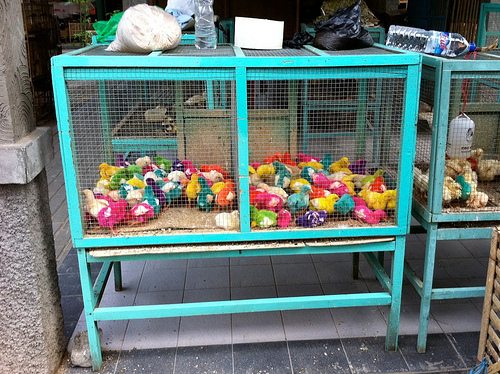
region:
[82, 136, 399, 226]
stuffed animals of all different colors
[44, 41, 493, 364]
two blue cages stuffed animals are in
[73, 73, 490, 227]
wire on the cages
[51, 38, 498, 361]
blue frames of the cages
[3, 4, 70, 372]
cement column next to cage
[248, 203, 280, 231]
green and white stuffed animal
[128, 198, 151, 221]
pink and white stuffed animal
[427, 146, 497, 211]
stuffed teddy bears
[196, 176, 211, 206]
teal and white stuffed animal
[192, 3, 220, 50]
water bottle on top of cage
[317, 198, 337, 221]
baby chick is dyed yellow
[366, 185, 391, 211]
baby chick is dyed yellow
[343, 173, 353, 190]
baby chick is dyed yellow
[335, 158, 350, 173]
baby chick is dyed yellow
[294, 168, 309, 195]
baby chick is dyed yellow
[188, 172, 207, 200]
baby chick is dyed yellow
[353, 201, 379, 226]
baby chick is dyed pink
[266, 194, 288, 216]
baby chick is dyed pink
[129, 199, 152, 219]
baby chick is dyed pink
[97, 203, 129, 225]
baby chick is dyed pink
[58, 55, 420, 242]
a cage full of baby chickens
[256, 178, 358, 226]
baby chicks are in many colors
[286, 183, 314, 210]
one chicken is blue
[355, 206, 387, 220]
one chicken is pink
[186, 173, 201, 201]
one chicken is yellow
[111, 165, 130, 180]
a chicken is green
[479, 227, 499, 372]
a wooden pallet in bottom left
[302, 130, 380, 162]
cage has small holes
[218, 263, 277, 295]
white tiles on floor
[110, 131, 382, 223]
baby easter chicks in pen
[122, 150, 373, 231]
baby easter chicks in pen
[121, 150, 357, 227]
baby easter chicks in pen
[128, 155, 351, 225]
baby easter chicks in pen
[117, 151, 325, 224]
baby easter chicks in pen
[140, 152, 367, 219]
baby easter chicks in pen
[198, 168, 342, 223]
baby easter chicks in pen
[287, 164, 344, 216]
baby easter chicks in pen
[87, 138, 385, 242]
the chicks are colorful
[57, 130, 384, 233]
the chicks are colorful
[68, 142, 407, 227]
the chicks are colorful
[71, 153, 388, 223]
the chicks are colorful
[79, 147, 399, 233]
the chicks are colorful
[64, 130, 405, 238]
birds in the cage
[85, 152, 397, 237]
birds in the cage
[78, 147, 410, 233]
birds in the cage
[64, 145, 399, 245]
birds in the cage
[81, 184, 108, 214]
A small bird in a cage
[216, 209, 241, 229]
A small bird in a cage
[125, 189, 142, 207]
A small bird in a cage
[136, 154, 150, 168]
A small bird in a cage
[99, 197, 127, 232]
A small bird in a cage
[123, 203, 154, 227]
A small bird in a cage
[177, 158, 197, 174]
A small bird in a cage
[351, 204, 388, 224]
A small bird in a cage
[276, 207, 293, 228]
A small bird in a cage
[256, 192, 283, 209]
A small bird in a cage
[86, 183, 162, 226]
birds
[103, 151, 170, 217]
birds in the cage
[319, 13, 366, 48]
a bag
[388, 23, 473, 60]
a bottle